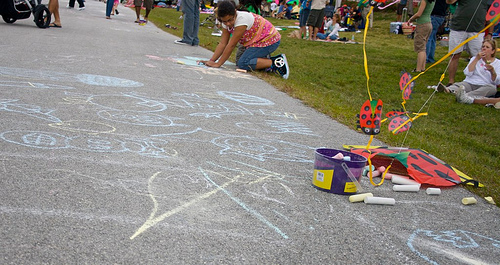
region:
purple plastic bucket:
[310, 141, 368, 204]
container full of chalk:
[309, 140, 371, 205]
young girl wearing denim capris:
[202, 1, 296, 81]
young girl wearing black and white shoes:
[203, 3, 296, 85]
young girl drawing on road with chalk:
[201, 1, 312, 79]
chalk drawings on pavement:
[0, 61, 195, 168]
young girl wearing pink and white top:
[195, 0, 302, 85]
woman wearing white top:
[440, 32, 499, 104]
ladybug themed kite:
[342, 66, 481, 196]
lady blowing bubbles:
[435, 29, 497, 109]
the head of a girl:
[217, 2, 239, 31]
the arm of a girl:
[213, 15, 250, 64]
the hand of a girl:
[199, 56, 224, 71]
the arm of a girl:
[233, 37, 280, 76]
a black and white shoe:
[267, 49, 294, 81]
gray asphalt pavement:
[0, 0, 499, 264]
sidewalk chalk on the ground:
[343, 189, 400, 212]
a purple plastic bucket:
[308, 139, 371, 199]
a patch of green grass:
[126, 1, 498, 211]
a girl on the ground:
[196, 0, 296, 87]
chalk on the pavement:
[335, 185, 403, 239]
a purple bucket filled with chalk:
[300, 137, 372, 222]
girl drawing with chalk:
[145, 12, 286, 136]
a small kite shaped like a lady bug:
[319, 80, 394, 160]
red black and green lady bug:
[333, 95, 395, 160]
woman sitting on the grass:
[420, 33, 497, 139]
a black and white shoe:
[237, 39, 301, 123]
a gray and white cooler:
[376, 3, 412, 47]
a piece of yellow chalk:
[405, 187, 480, 245]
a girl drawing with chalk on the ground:
[200, 6, 298, 83]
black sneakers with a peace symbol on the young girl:
[269, 52, 291, 84]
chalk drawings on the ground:
[34, 70, 269, 222]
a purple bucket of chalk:
[308, 143, 368, 193]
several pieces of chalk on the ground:
[355, 186, 482, 214]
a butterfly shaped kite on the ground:
[372, 65, 467, 189]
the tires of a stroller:
[0, 0, 60, 27]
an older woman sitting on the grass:
[448, 28, 493, 107]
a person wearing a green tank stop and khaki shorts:
[410, 1, 435, 63]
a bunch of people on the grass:
[274, 5, 498, 83]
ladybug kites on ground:
[354, 73, 474, 188]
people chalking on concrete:
[2, 47, 499, 263]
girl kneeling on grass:
[200, 2, 298, 83]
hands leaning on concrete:
[192, 47, 226, 73]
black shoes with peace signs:
[269, 47, 291, 78]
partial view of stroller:
[3, 0, 56, 35]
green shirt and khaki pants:
[405, 0, 437, 75]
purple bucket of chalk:
[302, 144, 367, 192]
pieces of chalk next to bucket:
[334, 147, 479, 214]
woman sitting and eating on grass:
[440, 27, 499, 101]